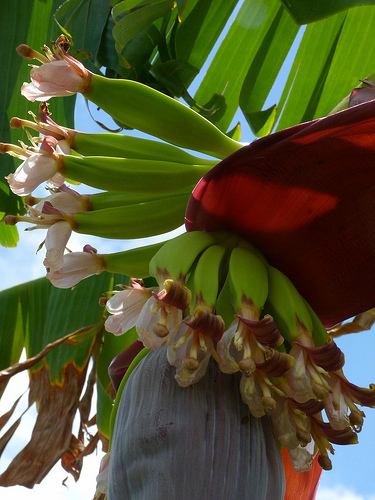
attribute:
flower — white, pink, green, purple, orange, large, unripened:
[16, 62, 100, 94]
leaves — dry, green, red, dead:
[100, 153, 203, 210]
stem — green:
[116, 86, 179, 119]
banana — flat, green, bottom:
[31, 23, 223, 60]